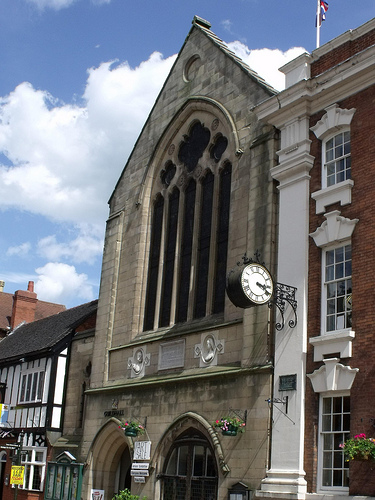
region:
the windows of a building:
[19, 373, 47, 399]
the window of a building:
[320, 412, 349, 483]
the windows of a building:
[177, 448, 207, 495]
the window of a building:
[320, 251, 353, 327]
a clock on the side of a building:
[222, 257, 300, 334]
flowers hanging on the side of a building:
[211, 406, 251, 438]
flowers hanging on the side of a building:
[118, 416, 150, 437]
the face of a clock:
[238, 262, 273, 305]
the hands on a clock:
[253, 280, 272, 296]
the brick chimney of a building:
[10, 278, 42, 328]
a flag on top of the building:
[310, 0, 328, 49]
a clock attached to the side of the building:
[219, 257, 303, 332]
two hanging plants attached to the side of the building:
[118, 413, 250, 441]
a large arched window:
[122, 98, 237, 338]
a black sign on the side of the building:
[276, 369, 297, 394]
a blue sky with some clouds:
[0, 140, 133, 308]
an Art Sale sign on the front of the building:
[132, 438, 151, 463]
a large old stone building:
[82, 2, 282, 499]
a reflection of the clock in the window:
[332, 281, 356, 324]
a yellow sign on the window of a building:
[8, 464, 26, 485]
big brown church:
[97, 45, 270, 497]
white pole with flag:
[313, 3, 328, 48]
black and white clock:
[224, 263, 275, 310]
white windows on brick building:
[309, 103, 360, 496]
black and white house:
[0, 294, 102, 490]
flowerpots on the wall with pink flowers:
[123, 417, 371, 460]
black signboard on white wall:
[274, 371, 295, 392]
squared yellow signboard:
[11, 463, 24, 486]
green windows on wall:
[42, 457, 82, 499]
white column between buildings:
[257, 50, 310, 498]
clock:
[234, 255, 272, 314]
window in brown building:
[138, 115, 228, 313]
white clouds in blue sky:
[0, 8, 80, 86]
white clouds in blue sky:
[5, 69, 93, 152]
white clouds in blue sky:
[5, 172, 69, 244]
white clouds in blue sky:
[10, 210, 83, 274]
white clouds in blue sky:
[95, 18, 156, 79]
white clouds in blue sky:
[231, 11, 304, 50]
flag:
[300, 8, 326, 42]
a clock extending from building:
[169, 186, 361, 366]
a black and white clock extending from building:
[207, 210, 359, 405]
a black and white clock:
[229, 225, 314, 365]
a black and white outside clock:
[190, 225, 348, 363]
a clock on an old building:
[196, 210, 373, 383]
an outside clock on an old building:
[181, 207, 370, 417]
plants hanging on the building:
[89, 368, 314, 497]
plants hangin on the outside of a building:
[100, 378, 332, 477]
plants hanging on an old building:
[94, 367, 276, 468]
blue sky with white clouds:
[17, 64, 171, 240]